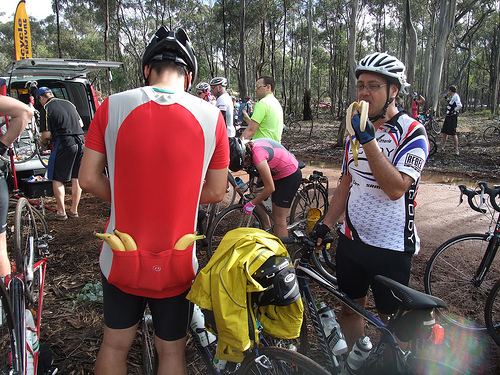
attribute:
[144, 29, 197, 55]
helmet — black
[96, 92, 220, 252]
shirt — red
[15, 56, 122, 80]
door — open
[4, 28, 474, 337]
bicyclist — standing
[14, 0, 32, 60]
sign — yellow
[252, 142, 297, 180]
shirt — pink